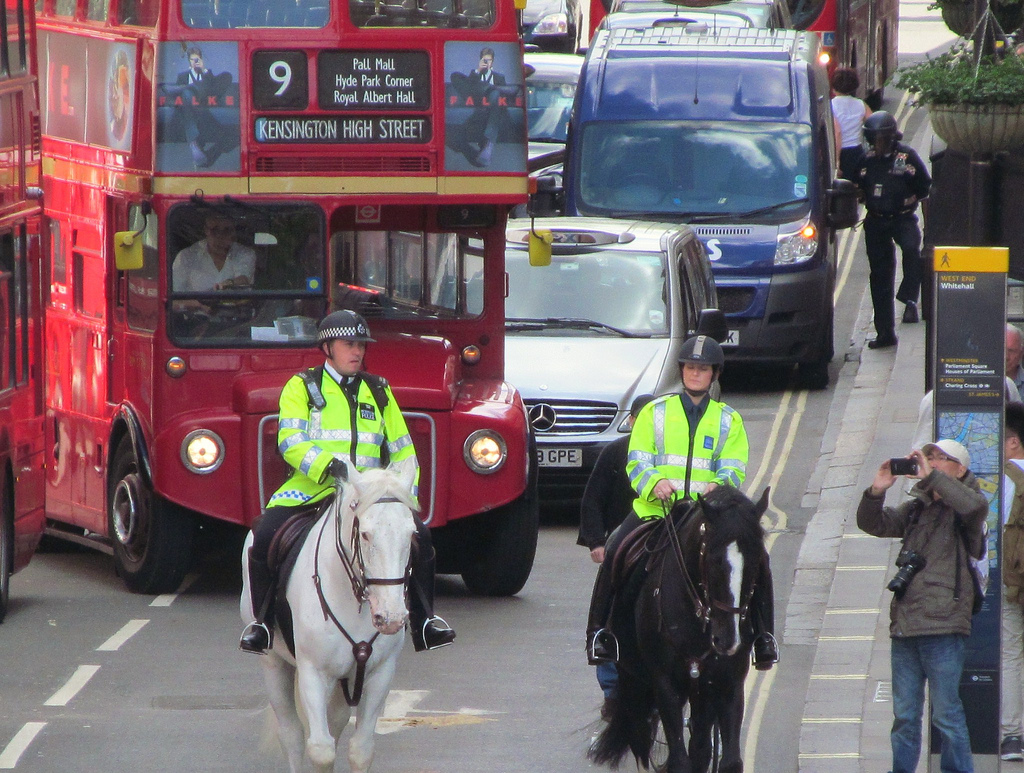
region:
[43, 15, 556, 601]
a red double-decker bus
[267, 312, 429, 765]
a policeman on a white horse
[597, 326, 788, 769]
a policeman on a black horse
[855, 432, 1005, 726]
a person holding a camera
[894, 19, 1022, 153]
a plant in a pot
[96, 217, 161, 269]
a yellow mirror on a bus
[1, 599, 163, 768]
white lines in the street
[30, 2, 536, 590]
a tall red bus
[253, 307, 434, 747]
a man on a horse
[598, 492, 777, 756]
a black horse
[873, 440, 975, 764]
a man taking a picture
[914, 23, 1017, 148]
a plant hanging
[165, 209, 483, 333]
the windshield on the bus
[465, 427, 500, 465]
the headlight on the bus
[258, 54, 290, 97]
the number on the bus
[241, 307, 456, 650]
the man wearing a hard hat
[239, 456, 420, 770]
the horse is white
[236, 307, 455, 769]
the man on the horse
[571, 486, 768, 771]
the horse is black with a white mark on his face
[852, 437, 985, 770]
the man holding a camera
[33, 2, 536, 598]
the bus is red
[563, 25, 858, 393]
the van is blue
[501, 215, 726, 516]
the car is silver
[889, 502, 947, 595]
the camera has a long lens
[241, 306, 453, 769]
a man sitting on a white horse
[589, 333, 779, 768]
a woman sitting on a black horse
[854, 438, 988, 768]
a man with a white cap taking a picture with a camera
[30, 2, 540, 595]
a red double-decker us changing lane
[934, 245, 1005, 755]
a long vertical sign with a yellow top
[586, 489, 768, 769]
horse has a white nose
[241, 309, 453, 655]
man is wearing a black helmet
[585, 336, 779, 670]
woman wearing a yellow security jacket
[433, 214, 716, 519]
silver car riving down the street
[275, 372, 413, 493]
A man wearing a yellow jacket.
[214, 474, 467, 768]
A horse that is white.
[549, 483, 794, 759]
A horse that is black.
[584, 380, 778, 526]
A woman that is wearing a yellow jacket.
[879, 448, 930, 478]
A man holding a camera.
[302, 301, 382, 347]
A man that is wearing a black helmet.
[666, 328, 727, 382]
A woman that is wearing a black helmet.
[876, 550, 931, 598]
A camera around the man's neck.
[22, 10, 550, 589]
A red bus behind the horses.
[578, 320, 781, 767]
police woman riding a horse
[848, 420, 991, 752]
tourist taking a photo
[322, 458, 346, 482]
hand gripping a horse reign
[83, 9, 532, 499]
large red double decker bus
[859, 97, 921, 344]
policeman standing on sidewalk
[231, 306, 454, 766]
Police officer on a white horse.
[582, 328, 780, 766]
Police officer on a brown and white horse.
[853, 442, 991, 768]
Man holding up phone.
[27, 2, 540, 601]
A red double decker bus.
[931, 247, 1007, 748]
A post on the street with a map.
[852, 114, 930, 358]
A man wearing a helmet on the side of the street.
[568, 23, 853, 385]
A blue van waiting in traffic.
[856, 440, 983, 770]
A man wearing a white hat.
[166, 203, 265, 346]
A man driving a bus.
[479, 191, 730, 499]
a silver mini van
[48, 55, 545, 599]
a large red bus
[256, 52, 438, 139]
the sign on the bus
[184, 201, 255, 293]
the person driving the bus